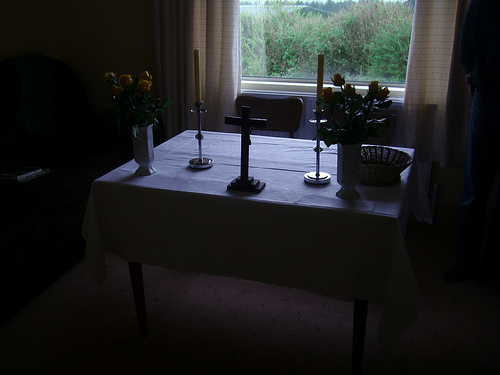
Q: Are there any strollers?
A: No, there are no strollers.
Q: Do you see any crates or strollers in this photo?
A: No, there are no strollers or crates.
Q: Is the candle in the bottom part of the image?
A: No, the candle is in the top of the image.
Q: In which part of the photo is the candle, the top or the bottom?
A: The candle is in the top of the image.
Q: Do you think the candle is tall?
A: Yes, the candle is tall.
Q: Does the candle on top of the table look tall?
A: Yes, the candle is tall.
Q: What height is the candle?
A: The candle is tall.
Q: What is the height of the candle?
A: The candle is tall.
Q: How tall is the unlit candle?
A: The candle is tall.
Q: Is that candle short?
A: No, the candle is tall.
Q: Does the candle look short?
A: No, the candle is tall.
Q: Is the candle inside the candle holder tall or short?
A: The candle is tall.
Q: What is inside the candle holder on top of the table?
A: The candle is inside the candle holder.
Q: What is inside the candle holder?
A: The candle is inside the candle holder.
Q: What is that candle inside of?
A: The candle is inside the candle holder.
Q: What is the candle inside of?
A: The candle is inside the candle holder.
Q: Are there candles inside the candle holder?
A: Yes, there is a candle inside the candle holder.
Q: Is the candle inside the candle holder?
A: Yes, the candle is inside the candle holder.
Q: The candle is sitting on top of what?
A: The candle is sitting on top of the table.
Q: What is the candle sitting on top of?
A: The candle is sitting on top of the table.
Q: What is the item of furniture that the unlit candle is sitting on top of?
A: The piece of furniture is a table.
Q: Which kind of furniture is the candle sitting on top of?
A: The candle is sitting on top of the table.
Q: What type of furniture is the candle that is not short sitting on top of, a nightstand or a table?
A: The candle is sitting on top of a table.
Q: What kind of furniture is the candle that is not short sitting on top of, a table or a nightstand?
A: The candle is sitting on top of a table.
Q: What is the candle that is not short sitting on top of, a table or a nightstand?
A: The candle is sitting on top of a table.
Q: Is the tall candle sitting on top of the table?
A: Yes, the candle is sitting on top of the table.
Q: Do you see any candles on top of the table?
A: Yes, there is a candle on top of the table.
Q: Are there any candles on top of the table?
A: Yes, there is a candle on top of the table.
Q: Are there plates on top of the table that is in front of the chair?
A: No, there is a candle on top of the table.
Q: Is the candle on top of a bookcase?
A: No, the candle is on top of a table.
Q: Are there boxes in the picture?
A: No, there are no boxes.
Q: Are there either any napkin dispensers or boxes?
A: No, there are no boxes or napkin dispensers.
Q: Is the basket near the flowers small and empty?
A: Yes, the basket is small and empty.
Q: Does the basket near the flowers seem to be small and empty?
A: Yes, the basket is small and empty.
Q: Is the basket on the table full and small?
A: No, the basket is small but empty.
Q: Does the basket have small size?
A: Yes, the basket is small.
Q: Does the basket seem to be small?
A: Yes, the basket is small.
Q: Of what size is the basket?
A: The basket is small.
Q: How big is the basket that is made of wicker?
A: The basket is small.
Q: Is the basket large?
A: No, the basket is small.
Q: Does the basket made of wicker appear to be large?
A: No, the basket is small.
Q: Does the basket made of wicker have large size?
A: No, the basket is small.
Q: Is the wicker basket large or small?
A: The basket is small.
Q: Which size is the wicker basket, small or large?
A: The basket is small.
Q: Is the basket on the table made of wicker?
A: Yes, the basket is made of wicker.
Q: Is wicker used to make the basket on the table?
A: Yes, the basket is made of wicker.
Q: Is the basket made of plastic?
A: No, the basket is made of wicker.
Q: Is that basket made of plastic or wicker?
A: The basket is made of wicker.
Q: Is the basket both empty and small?
A: Yes, the basket is empty and small.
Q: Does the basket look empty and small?
A: Yes, the basket is empty and small.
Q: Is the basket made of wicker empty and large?
A: No, the basket is empty but small.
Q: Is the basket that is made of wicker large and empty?
A: No, the basket is empty but small.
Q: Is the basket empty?
A: Yes, the basket is empty.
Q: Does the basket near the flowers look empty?
A: Yes, the basket is empty.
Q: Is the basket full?
A: No, the basket is empty.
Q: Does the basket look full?
A: No, the basket is empty.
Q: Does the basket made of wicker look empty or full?
A: The basket is empty.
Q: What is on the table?
A: The basket is on the table.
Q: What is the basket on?
A: The basket is on the table.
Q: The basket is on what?
A: The basket is on the table.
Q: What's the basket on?
A: The basket is on the table.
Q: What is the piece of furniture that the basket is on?
A: The piece of furniture is a table.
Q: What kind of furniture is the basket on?
A: The basket is on the table.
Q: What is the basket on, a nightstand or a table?
A: The basket is on a table.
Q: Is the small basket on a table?
A: Yes, the basket is on a table.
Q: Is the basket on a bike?
A: No, the basket is on a table.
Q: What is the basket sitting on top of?
A: The basket is sitting on top of the table.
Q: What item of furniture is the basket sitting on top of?
A: The basket is sitting on top of the table.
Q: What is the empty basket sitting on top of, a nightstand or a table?
A: The basket is sitting on top of a table.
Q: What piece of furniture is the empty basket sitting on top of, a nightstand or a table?
A: The basket is sitting on top of a table.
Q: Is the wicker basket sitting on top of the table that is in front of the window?
A: Yes, the basket is sitting on top of the table.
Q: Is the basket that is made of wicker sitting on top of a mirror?
A: No, the basket is sitting on top of the table.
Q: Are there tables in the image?
A: Yes, there is a table.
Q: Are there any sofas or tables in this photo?
A: Yes, there is a table.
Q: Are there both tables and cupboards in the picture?
A: No, there is a table but no cupboards.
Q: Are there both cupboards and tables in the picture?
A: No, there is a table but no cupboards.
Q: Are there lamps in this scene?
A: No, there are no lamps.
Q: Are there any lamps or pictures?
A: No, there are no lamps or pictures.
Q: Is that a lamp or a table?
A: That is a table.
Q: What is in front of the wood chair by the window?
A: The table is in front of the chair.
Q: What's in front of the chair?
A: The table is in front of the chair.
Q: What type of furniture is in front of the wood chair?
A: The piece of furniture is a table.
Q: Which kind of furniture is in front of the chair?
A: The piece of furniture is a table.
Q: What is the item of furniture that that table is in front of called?
A: The piece of furniture is a chair.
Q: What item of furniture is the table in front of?
A: The table is in front of the chair.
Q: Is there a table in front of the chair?
A: Yes, there is a table in front of the chair.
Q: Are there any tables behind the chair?
A: No, the table is in front of the chair.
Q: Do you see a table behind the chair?
A: No, the table is in front of the chair.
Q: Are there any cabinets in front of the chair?
A: No, there is a table in front of the chair.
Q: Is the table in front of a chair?
A: Yes, the table is in front of a chair.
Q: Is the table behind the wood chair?
A: No, the table is in front of the chair.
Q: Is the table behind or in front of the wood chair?
A: The table is in front of the chair.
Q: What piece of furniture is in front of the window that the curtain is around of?
A: The piece of furniture is a table.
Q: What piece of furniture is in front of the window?
A: The piece of furniture is a table.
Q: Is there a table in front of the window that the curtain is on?
A: Yes, there is a table in front of the window.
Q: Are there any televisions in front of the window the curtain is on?
A: No, there is a table in front of the window.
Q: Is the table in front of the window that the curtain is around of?
A: Yes, the table is in front of the window.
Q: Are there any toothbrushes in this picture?
A: No, there are no toothbrushes.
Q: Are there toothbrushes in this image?
A: No, there are no toothbrushes.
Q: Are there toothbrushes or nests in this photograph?
A: No, there are no toothbrushes or nests.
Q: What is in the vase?
A: The flowers are in the vase.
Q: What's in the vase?
A: The flowers are in the vase.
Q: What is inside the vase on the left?
A: The flowers are inside the vase.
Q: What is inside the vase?
A: The flowers are inside the vase.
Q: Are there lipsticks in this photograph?
A: No, there are no lipsticks.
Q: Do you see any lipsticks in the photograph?
A: No, there are no lipsticks.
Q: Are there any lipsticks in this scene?
A: No, there are no lipsticks.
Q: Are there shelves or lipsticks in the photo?
A: No, there are no lipsticks or shelves.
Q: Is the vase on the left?
A: Yes, the vase is on the left of the image.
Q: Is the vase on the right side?
A: No, the vase is on the left of the image.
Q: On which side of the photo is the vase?
A: The vase is on the left of the image.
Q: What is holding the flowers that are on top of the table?
A: The vase is holding the flowers.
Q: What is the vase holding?
A: The vase is holding the flowers.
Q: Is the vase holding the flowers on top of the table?
A: Yes, the vase is holding the flowers.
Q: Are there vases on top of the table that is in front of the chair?
A: Yes, there is a vase on top of the table.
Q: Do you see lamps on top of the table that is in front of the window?
A: No, there is a vase on top of the table.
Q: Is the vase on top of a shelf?
A: No, the vase is on top of a table.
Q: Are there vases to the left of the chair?
A: Yes, there is a vase to the left of the chair.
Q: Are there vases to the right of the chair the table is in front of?
A: No, the vase is to the left of the chair.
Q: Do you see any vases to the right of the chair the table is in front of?
A: No, the vase is to the left of the chair.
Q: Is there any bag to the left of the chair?
A: No, there is a vase to the left of the chair.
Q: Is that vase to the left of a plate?
A: No, the vase is to the left of the chair.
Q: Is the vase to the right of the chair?
A: No, the vase is to the left of the chair.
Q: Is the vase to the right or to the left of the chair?
A: The vase is to the left of the chair.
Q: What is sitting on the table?
A: The vase is sitting on the table.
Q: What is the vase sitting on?
A: The vase is sitting on the table.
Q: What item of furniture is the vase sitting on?
A: The vase is sitting on the table.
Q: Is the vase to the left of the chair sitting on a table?
A: Yes, the vase is sitting on a table.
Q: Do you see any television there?
A: No, there are no televisions.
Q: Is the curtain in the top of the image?
A: Yes, the curtain is in the top of the image.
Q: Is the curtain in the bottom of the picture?
A: No, the curtain is in the top of the image.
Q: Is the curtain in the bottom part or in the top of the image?
A: The curtain is in the top of the image.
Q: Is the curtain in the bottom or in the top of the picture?
A: The curtain is in the top of the image.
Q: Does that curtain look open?
A: Yes, the curtain is open.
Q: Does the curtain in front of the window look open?
A: Yes, the curtain is open.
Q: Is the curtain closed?
A: No, the curtain is open.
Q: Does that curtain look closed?
A: No, the curtain is open.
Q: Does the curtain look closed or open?
A: The curtain is open.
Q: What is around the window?
A: The curtain is around the window.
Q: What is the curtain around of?
A: The curtain is around the window.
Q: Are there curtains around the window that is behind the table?
A: Yes, there is a curtain around the window.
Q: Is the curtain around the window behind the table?
A: Yes, the curtain is around the window.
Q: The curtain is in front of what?
A: The curtain is in front of the window.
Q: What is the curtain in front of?
A: The curtain is in front of the window.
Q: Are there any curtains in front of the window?
A: Yes, there is a curtain in front of the window.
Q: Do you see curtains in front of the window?
A: Yes, there is a curtain in front of the window.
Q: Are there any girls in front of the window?
A: No, there is a curtain in front of the window.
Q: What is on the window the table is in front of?
A: The curtain is on the window.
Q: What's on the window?
A: The curtain is on the window.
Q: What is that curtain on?
A: The curtain is on the window.